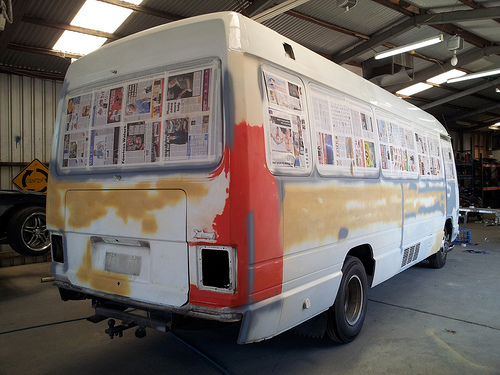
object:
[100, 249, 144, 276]
license plate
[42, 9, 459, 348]
van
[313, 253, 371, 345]
tire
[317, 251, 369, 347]
wheel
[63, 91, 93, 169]
newspaper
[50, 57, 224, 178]
back window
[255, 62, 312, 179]
side windows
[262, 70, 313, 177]
newspaper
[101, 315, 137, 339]
towing hitch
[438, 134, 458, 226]
front side door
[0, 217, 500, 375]
floor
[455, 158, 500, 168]
shelves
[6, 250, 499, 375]
road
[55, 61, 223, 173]
mirror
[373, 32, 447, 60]
light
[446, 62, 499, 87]
light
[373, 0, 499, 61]
rods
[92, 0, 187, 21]
rods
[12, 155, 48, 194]
board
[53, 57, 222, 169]
window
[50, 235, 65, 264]
bumper light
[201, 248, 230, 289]
bumper light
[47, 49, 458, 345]
fainted paint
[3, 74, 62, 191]
wall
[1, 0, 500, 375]
building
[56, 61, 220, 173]
rear window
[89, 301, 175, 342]
trailer hitch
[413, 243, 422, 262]
air vents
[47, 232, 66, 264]
hole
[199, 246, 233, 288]
hole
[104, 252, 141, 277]
area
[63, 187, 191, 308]
access door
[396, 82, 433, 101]
sky lights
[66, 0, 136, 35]
sky lights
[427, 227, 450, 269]
wheel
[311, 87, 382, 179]
side window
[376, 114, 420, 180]
side window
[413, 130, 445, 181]
side window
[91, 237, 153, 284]
holder